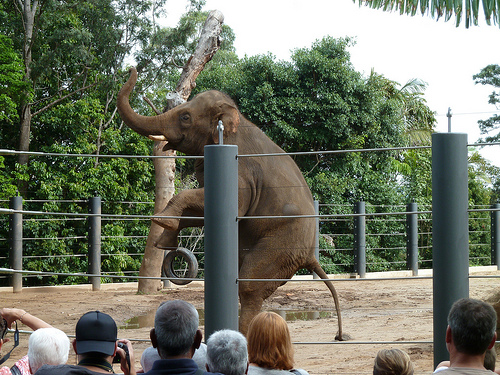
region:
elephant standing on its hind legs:
[112, 65, 336, 361]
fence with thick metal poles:
[20, 196, 452, 273]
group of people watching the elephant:
[23, 300, 480, 373]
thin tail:
[308, 255, 363, 342]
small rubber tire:
[163, 247, 200, 286]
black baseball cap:
[71, 313, 119, 362]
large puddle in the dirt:
[124, 290, 349, 329]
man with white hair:
[201, 332, 251, 372]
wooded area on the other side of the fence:
[6, 21, 452, 276]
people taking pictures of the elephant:
[0, 313, 134, 373]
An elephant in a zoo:
[114, 63, 348, 347]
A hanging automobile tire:
[161, 250, 200, 284]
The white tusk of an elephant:
[142, 128, 171, 146]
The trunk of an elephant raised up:
[114, 66, 147, 146]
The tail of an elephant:
[308, 258, 350, 343]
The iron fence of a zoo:
[353, 201, 419, 276]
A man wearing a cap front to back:
[71, 309, 118, 361]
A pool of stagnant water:
[283, 302, 335, 322]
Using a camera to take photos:
[99, 327, 136, 367]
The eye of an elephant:
[178, 103, 196, 127]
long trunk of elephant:
[108, 63, 168, 133]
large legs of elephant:
[145, 190, 215, 262]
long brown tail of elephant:
[301, 270, 358, 350]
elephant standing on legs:
[112, 60, 334, 319]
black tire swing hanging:
[168, 250, 199, 281]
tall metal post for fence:
[187, 144, 247, 316]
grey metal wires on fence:
[3, 154, 195, 281]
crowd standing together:
[7, 306, 314, 373]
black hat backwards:
[73, 312, 118, 355]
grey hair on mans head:
[198, 321, 246, 373]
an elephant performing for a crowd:
[105, 61, 373, 355]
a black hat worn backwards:
[62, 307, 134, 372]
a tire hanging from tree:
[153, 238, 203, 292]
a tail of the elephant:
[304, 255, 361, 358]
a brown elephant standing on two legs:
[90, 52, 371, 334]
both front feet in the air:
[132, 175, 233, 268]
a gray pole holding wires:
[183, 140, 255, 358]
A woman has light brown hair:
[241, 303, 311, 373]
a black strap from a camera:
[1, 311, 25, 365]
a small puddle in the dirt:
[128, 291, 333, 326]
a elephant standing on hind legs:
[108, 64, 310, 353]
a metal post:
[201, 139, 241, 321]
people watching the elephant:
[6, 312, 295, 373]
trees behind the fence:
[291, 53, 435, 151]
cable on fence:
[295, 138, 438, 161]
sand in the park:
[354, 271, 419, 336]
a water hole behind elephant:
[285, 285, 350, 322]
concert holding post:
[358, 264, 446, 279]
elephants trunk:
[106, 64, 226, 137]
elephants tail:
[305, 244, 350, 337]